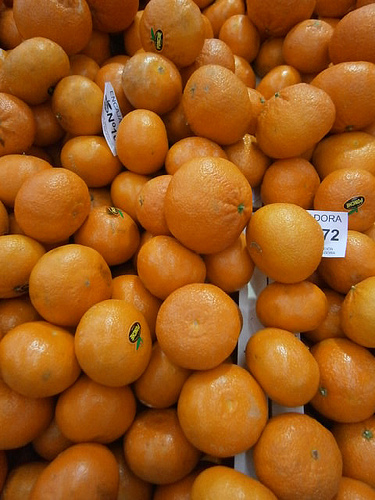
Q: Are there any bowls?
A: No, there are no bowls.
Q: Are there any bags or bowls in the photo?
A: No, there are no bowls or bags.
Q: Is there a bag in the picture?
A: No, there are no bags.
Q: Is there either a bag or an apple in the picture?
A: No, there are no bags or apples.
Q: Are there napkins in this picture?
A: No, there are no napkins.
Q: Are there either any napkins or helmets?
A: No, there are no napkins or helmets.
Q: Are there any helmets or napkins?
A: No, there are no napkins or helmets.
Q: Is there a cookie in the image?
A: No, there are no cookies.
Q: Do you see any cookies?
A: No, there are no cookies.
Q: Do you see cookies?
A: No, there are no cookies.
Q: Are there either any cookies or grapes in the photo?
A: No, there are no cookies or grapes.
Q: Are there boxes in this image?
A: No, there are no boxes.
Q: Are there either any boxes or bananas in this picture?
A: No, there are no boxes or bananas.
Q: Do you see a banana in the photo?
A: No, there are no bananas.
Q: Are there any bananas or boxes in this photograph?
A: No, there are no bananas or boxes.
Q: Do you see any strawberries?
A: No, there are no strawberries.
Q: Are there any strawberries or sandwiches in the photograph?
A: No, there are no strawberries or sandwiches.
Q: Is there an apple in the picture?
A: No, there are no apples.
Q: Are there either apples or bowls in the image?
A: No, there are no apples or bowls.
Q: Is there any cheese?
A: No, there is no cheese.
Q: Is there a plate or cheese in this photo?
A: No, there are no cheese or plates.